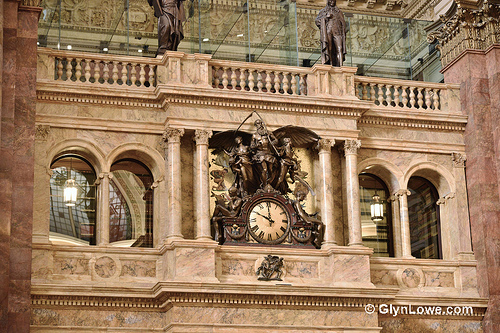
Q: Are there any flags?
A: No, there are no flags.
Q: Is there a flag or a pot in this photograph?
A: No, there are no flags or pots.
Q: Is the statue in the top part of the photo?
A: Yes, the statue is in the top of the image.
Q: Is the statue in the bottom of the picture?
A: No, the statue is in the top of the image.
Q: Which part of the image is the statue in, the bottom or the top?
A: The statue is in the top of the image.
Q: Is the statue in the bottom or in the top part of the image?
A: The statue is in the top of the image.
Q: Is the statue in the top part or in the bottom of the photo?
A: The statue is in the top of the image.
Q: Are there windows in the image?
A: Yes, there is a window.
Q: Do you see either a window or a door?
A: Yes, there is a window.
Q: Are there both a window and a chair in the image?
A: No, there is a window but no chairs.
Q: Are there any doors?
A: No, there are no doors.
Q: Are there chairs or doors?
A: No, there are no doors or chairs.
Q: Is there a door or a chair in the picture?
A: No, there are no doors or chairs.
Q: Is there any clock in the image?
A: Yes, there is a clock.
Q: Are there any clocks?
A: Yes, there is a clock.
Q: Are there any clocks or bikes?
A: Yes, there is a clock.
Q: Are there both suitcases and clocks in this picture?
A: No, there is a clock but no suitcases.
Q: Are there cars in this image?
A: No, there are no cars.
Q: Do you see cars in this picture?
A: No, there are no cars.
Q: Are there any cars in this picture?
A: No, there are no cars.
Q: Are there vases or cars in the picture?
A: No, there are no cars or vases.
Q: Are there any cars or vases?
A: No, there are no cars or vases.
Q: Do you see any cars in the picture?
A: No, there are no cars.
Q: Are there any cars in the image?
A: No, there are no cars.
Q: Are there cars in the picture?
A: No, there are no cars.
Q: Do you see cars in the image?
A: No, there are no cars.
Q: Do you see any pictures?
A: No, there are no pictures.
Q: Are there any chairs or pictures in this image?
A: No, there are no pictures or chairs.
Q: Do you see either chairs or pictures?
A: No, there are no pictures or chairs.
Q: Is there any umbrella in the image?
A: No, there are no umbrellas.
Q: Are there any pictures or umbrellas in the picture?
A: No, there are no umbrellas or pictures.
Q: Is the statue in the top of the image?
A: Yes, the statue is in the top of the image.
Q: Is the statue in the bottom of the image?
A: No, the statue is in the top of the image.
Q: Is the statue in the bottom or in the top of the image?
A: The statue is in the top of the image.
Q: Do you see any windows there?
A: Yes, there is a window.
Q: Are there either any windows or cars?
A: Yes, there is a window.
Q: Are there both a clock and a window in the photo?
A: Yes, there are both a window and a clock.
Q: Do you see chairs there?
A: No, there are no chairs.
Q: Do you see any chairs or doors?
A: No, there are no chairs or doors.